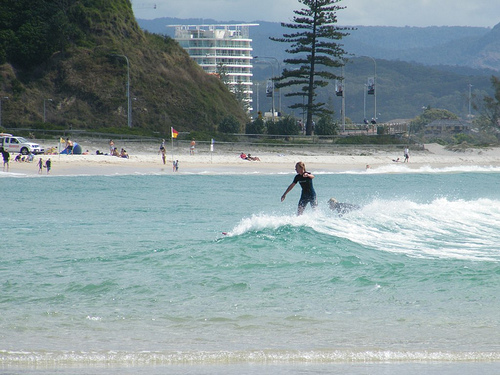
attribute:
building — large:
[162, 18, 259, 133]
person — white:
[279, 161, 321, 219]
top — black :
[292, 172, 316, 193]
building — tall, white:
[160, 15, 256, 120]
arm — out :
[278, 172, 336, 195]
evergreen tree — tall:
[277, 17, 345, 122]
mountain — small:
[0, 1, 260, 143]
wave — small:
[65, 173, 243, 362]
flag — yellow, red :
[168, 125, 178, 154]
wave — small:
[218, 204, 470, 241]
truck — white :
[1, 129, 41, 159]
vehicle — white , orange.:
[2, 132, 47, 157]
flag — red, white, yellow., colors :
[169, 127, 180, 139]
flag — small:
[169, 124, 179, 139]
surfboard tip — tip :
[219, 226, 234, 239]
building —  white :
[158, 21, 263, 123]